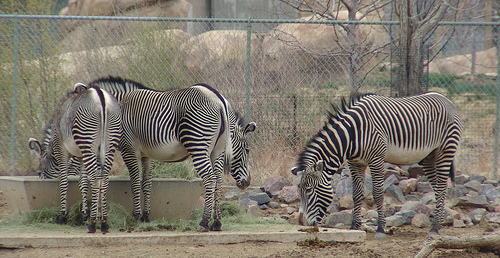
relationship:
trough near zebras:
[6, 167, 229, 218] [50, 82, 232, 241]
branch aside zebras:
[406, 225, 500, 246] [50, 82, 232, 241]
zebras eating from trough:
[50, 82, 232, 241] [6, 167, 229, 218]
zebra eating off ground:
[290, 81, 454, 236] [282, 226, 364, 257]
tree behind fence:
[290, 3, 449, 92] [11, 22, 482, 78]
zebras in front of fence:
[50, 82, 232, 241] [11, 22, 482, 78]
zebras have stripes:
[50, 82, 232, 241] [136, 100, 181, 159]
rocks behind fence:
[53, 40, 383, 76] [11, 22, 482, 78]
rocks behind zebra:
[302, 157, 497, 211] [290, 81, 454, 236]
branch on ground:
[406, 225, 500, 246] [282, 226, 364, 257]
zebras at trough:
[50, 82, 232, 241] [6, 167, 229, 218]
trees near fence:
[290, 3, 449, 92] [11, 22, 482, 78]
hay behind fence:
[204, 61, 339, 120] [11, 22, 482, 78]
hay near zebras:
[51, 196, 237, 230] [50, 82, 232, 241]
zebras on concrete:
[50, 82, 232, 241] [5, 230, 372, 244]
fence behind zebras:
[11, 22, 482, 78] [50, 82, 232, 241]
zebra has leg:
[290, 81, 454, 236] [361, 142, 398, 230]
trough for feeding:
[6, 167, 229, 218] [35, 147, 93, 205]